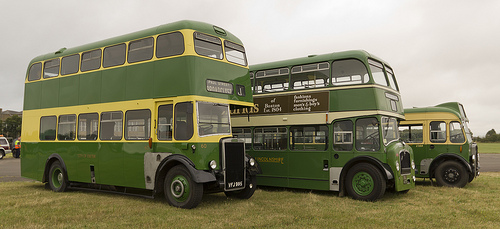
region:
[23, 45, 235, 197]
bus has two tiers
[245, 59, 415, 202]
this is a tourist bus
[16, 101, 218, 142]
yellow around the windows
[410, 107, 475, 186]
smaller bus is yellow and green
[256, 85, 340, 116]
writing on the side of bus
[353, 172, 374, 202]
green wheels on tires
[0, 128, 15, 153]
white rear of car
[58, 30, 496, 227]
buses on the grass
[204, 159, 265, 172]
headlights on the front of bus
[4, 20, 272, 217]
a double decker bus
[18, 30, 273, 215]
a double decker bus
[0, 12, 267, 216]
a double decker bus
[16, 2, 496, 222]
the buses are parked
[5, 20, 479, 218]
the buses are parked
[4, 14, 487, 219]
the buses are parked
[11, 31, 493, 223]
the buses are parked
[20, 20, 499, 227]
the buses are parked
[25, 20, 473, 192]
Three yellow and green buses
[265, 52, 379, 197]
Bus made out of two stacked bus frames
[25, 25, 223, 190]
Green bus with yellow trim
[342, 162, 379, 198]
Bus tire with green wheels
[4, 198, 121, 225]
Dry yellow and green grass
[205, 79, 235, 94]
Black sign with white lettering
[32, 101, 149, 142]
Bus with large windows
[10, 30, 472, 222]
Buses parked on grass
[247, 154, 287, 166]
Yellow lettering on side of green bus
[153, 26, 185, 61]
Small window on a bus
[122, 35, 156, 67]
Small window on a bus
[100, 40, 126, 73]
Small window on a bus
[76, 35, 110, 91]
Small window on a bus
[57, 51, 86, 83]
Small window on a bus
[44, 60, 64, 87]
Small window on a bus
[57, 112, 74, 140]
Small window on a bus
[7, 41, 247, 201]
Bus on the grass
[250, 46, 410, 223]
Bus on the grass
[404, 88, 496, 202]
Bus on the grass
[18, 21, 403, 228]
two double decker buses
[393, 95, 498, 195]
one regular bus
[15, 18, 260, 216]
a green and yellow bus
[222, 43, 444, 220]
a green and tan bus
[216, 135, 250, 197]
a black grill on the front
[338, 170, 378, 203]
green rim on wheel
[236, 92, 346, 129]
brown and white sign on bus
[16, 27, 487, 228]
three similar buses but different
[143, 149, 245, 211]
black fender over wheel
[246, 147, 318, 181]
yellow writing on bus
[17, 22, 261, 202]
Double decker bus is parked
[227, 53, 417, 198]
Double decker bus is parked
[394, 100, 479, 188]
Bus parked next to a bus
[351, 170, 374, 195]
Green wheel on the black tire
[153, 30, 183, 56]
A window on a bus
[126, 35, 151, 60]
A window on a bus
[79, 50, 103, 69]
A window on a bus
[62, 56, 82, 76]
A window on a bus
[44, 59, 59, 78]
A window on a bus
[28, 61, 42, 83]
A window on a bus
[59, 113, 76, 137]
A window on a bus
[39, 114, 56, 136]
A window on a bus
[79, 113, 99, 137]
A window on a bus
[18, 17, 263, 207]
a green and yellow double decker bus